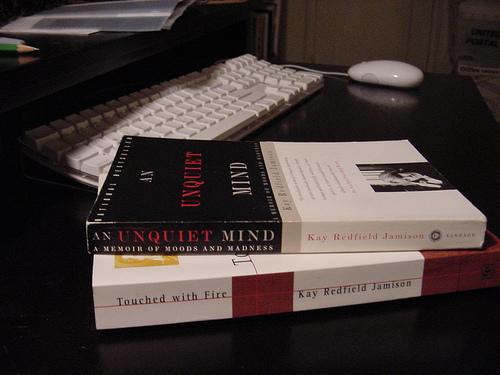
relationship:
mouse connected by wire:
[348, 58, 425, 90] [279, 62, 347, 78]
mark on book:
[112, 250, 181, 267] [92, 173, 499, 330]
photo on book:
[355, 163, 455, 194] [85, 135, 488, 250]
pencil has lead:
[0, 41, 39, 54] [32, 46, 39, 53]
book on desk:
[85, 135, 488, 250] [1, 3, 499, 374]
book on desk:
[92, 173, 499, 330] [1, 3, 499, 374]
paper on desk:
[1, 0, 203, 38] [1, 3, 499, 374]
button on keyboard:
[22, 123, 60, 150] [16, 52, 325, 190]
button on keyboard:
[43, 136, 72, 162] [16, 52, 325, 190]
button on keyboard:
[62, 143, 99, 169] [16, 52, 325, 190]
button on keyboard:
[81, 154, 115, 176] [16, 52, 325, 190]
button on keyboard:
[50, 117, 76, 135] [16, 52, 325, 190]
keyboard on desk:
[16, 52, 325, 190] [1, 3, 499, 374]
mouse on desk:
[348, 58, 425, 90] [1, 3, 499, 374]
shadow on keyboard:
[14, 65, 220, 184] [16, 52, 325, 190]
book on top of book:
[85, 135, 488, 250] [92, 173, 499, 330]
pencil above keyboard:
[0, 41, 39, 54] [16, 52, 325, 190]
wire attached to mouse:
[279, 62, 347, 78] [348, 58, 425, 90]